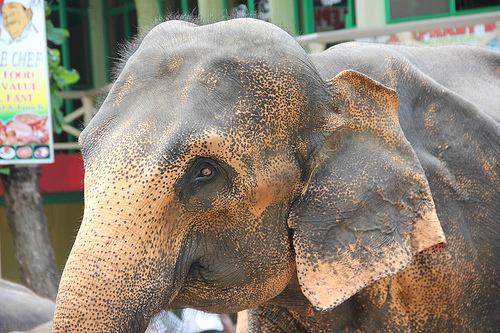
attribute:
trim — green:
[44, 1, 499, 41]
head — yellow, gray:
[44, 13, 328, 331]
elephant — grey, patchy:
[101, 56, 480, 326]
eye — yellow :
[191, 155, 226, 184]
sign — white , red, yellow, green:
[0, 4, 57, 166]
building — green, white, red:
[5, 3, 499, 291]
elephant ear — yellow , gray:
[290, 65, 450, 309]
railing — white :
[44, 85, 133, 151]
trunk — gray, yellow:
[51, 206, 191, 332]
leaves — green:
[46, 24, 78, 131]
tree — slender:
[2, 159, 64, 304]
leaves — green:
[45, 18, 70, 45]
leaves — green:
[55, 62, 78, 84]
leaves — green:
[45, 47, 58, 70]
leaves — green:
[53, 108, 72, 128]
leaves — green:
[50, 117, 62, 134]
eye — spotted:
[190, 154, 220, 184]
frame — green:
[301, 2, 317, 34]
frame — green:
[380, 2, 484, 15]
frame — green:
[94, 7, 138, 38]